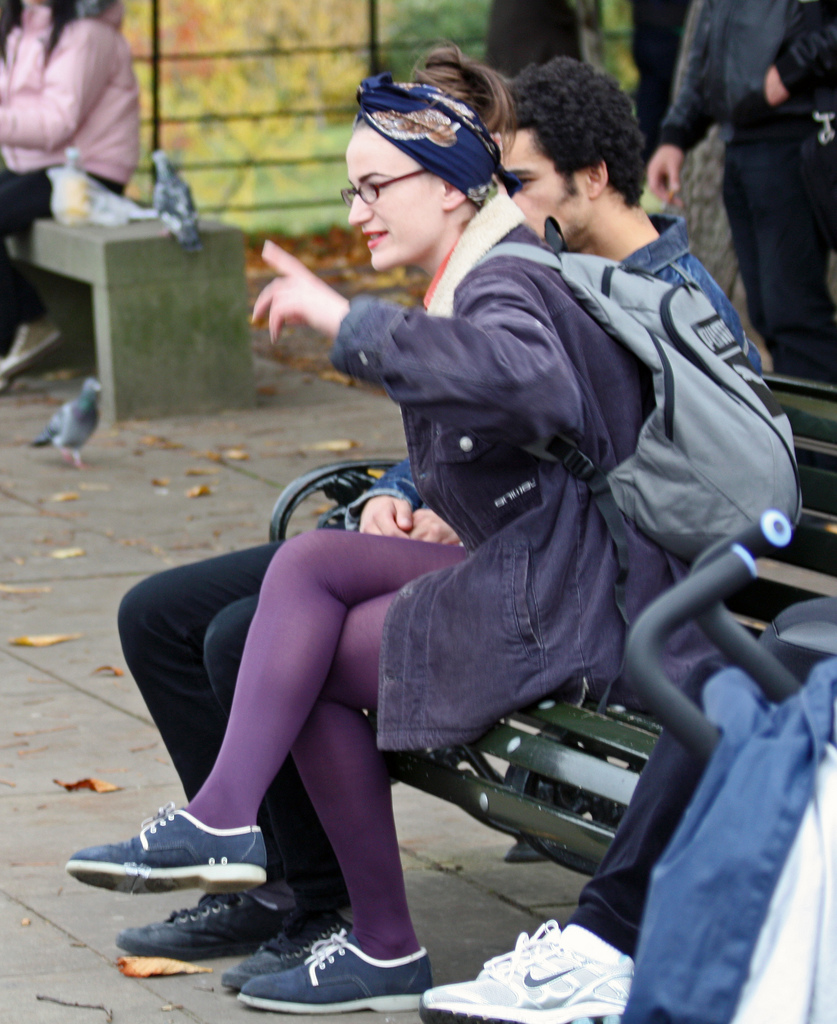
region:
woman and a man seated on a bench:
[64, 44, 832, 1020]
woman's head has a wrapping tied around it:
[65, 40, 717, 1007]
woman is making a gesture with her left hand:
[63, 39, 717, 1008]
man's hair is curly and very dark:
[114, 51, 754, 982]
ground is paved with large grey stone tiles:
[0, 346, 831, 1015]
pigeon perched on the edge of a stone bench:
[0, 149, 252, 420]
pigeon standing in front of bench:
[0, 208, 255, 467]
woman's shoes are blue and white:
[63, 44, 718, 1014]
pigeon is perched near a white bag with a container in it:
[46, 146, 203, 246]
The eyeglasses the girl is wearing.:
[341, 176, 430, 198]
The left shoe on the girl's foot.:
[72, 803, 276, 892]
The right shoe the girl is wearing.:
[238, 941, 434, 1011]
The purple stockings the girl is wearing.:
[188, 518, 466, 958]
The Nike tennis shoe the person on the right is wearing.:
[413, 919, 624, 1014]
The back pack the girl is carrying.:
[459, 218, 793, 550]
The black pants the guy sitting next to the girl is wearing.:
[116, 534, 351, 914]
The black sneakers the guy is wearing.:
[112, 887, 351, 980]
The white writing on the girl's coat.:
[481, 481, 541, 510]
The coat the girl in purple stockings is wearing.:
[327, 184, 719, 765]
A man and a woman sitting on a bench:
[64, 42, 790, 1017]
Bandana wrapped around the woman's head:
[352, 71, 500, 209]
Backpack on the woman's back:
[472, 217, 807, 561]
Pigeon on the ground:
[32, 366, 106, 464]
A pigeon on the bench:
[144, 142, 206, 266]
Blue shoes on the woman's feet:
[64, 801, 437, 1019]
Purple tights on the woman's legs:
[182, 531, 470, 969]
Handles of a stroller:
[624, 493, 802, 765]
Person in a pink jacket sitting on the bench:
[1, 0, 142, 403]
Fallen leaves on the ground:
[10, 392, 355, 986]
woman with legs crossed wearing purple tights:
[66, 38, 721, 1014]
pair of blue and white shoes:
[56, 798, 433, 1018]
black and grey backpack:
[463, 209, 807, 564]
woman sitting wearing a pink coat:
[1, 0, 139, 399]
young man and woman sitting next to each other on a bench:
[60, 42, 810, 1018]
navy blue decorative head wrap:
[345, 68, 500, 206]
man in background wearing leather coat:
[642, 1, 835, 389]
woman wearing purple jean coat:
[66, 42, 802, 1016]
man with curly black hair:
[117, 54, 760, 990]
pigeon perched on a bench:
[145, 145, 200, 250]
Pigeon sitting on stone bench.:
[131, 132, 211, 259]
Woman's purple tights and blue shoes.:
[59, 529, 436, 1009]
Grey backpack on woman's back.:
[546, 249, 806, 561]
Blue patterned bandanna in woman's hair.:
[355, 59, 503, 195]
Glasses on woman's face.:
[320, 168, 449, 212]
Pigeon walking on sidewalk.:
[23, 364, 129, 481]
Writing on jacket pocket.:
[485, 473, 536, 508]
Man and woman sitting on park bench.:
[50, 39, 803, 1015]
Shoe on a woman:
[63, 803, 274, 903]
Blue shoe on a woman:
[67, 805, 279, 899]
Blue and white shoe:
[63, 798, 275, 900]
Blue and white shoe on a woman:
[66, 801, 270, 896]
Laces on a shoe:
[164, 894, 221, 926]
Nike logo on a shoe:
[518, 958, 584, 993]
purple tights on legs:
[181, 525, 494, 962]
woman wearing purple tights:
[63, 41, 804, 1022]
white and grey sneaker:
[420, 915, 630, 1021]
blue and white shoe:
[68, 802, 271, 886]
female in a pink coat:
[2, 1, 151, 380]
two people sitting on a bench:
[65, 41, 826, 1013]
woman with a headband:
[340, 41, 528, 280]